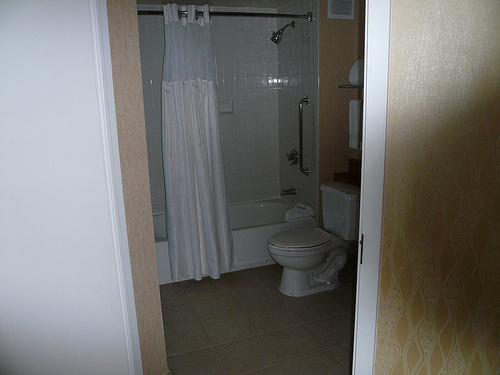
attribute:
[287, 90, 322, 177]
handle — metal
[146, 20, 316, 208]
shower — white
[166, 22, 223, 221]
curtain — white, silver, long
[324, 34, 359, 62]
wall — gold, brown, white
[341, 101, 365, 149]
towel — folded, hanging, white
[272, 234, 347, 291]
toilet — white, closed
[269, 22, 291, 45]
head — silver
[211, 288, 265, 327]
floor — brown, tile, tan